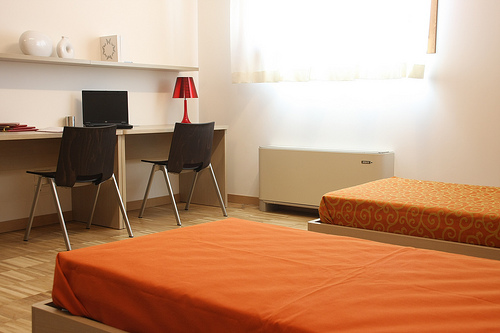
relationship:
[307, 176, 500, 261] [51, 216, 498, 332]
bed are covered in fabric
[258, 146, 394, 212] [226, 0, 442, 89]
radiator below window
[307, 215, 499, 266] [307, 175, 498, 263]
box beneath bed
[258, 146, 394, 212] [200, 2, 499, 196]
radiator next to wall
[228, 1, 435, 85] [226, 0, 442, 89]
curtain on window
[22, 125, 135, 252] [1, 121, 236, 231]
chair beside desk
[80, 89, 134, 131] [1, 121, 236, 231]
laptop sitting on desk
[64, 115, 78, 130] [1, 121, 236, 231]
cup sitting on desk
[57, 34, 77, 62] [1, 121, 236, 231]
sculpture on desk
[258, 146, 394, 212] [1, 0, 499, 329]
radiator in room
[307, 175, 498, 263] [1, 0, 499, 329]
bed sitting in a room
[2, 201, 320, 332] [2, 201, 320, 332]
floor covering floor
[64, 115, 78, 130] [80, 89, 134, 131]
cup sitting by computer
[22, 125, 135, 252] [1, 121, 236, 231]
chair next to desk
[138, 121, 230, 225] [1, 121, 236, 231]
chair next to desk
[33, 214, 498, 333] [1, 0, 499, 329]
bed sitting in room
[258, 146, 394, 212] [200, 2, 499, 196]
radiator against wall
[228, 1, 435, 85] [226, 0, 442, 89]
curtain covering window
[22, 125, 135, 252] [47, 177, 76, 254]
chair has a leg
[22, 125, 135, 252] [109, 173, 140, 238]
chair has a leg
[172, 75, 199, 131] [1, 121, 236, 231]
lamp sitting on a desk